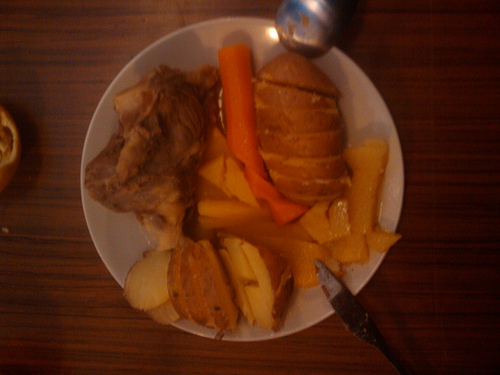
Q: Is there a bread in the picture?
A: Yes, there is a bread.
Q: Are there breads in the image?
A: Yes, there is a bread.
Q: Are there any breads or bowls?
A: Yes, there is a bread.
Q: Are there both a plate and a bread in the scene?
A: Yes, there are both a bread and a plate.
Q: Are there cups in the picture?
A: No, there are no cups.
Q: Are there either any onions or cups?
A: No, there are no cups or onions.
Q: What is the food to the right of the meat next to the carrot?
A: The food is a bread.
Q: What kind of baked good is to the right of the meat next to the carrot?
A: The food is a bread.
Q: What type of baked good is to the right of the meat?
A: The food is a bread.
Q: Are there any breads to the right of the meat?
A: Yes, there is a bread to the right of the meat.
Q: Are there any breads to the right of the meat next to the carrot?
A: Yes, there is a bread to the right of the meat.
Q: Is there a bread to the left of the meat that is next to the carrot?
A: No, the bread is to the right of the meat.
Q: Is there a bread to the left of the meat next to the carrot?
A: No, the bread is to the right of the meat.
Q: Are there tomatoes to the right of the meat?
A: No, there is a bread to the right of the meat.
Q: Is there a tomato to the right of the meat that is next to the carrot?
A: No, there is a bread to the right of the meat.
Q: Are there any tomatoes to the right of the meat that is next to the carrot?
A: No, there is a bread to the right of the meat.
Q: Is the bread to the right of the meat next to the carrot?
A: Yes, the bread is to the right of the meat.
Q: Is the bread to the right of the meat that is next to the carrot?
A: Yes, the bread is to the right of the meat.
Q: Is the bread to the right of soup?
A: No, the bread is to the right of the meat.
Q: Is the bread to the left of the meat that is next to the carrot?
A: No, the bread is to the right of the meat.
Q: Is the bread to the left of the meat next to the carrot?
A: No, the bread is to the right of the meat.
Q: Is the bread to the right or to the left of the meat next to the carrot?
A: The bread is to the right of the meat.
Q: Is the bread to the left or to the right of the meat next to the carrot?
A: The bread is to the right of the meat.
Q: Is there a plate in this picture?
A: Yes, there is a plate.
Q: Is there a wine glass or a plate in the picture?
A: Yes, there is a plate.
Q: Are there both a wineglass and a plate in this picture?
A: No, there is a plate but no wine glasses.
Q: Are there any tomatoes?
A: No, there are no tomatoes.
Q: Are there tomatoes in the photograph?
A: No, there are no tomatoes.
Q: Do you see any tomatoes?
A: No, there are no tomatoes.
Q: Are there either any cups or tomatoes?
A: No, there are no tomatoes or cups.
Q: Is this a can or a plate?
A: This is a plate.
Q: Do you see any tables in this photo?
A: Yes, there is a table.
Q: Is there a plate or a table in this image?
A: Yes, there is a table.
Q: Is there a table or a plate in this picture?
A: Yes, there is a table.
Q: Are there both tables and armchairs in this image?
A: No, there is a table but no armchairs.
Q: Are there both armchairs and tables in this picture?
A: No, there is a table but no armchairs.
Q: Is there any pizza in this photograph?
A: No, there are no pizzas.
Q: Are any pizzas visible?
A: No, there are no pizzas.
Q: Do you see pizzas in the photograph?
A: No, there are no pizzas.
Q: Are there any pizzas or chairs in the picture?
A: No, there are no pizzas or chairs.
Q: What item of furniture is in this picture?
A: The piece of furniture is a table.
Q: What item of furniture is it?
A: The piece of furniture is a table.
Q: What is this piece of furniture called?
A: This is a table.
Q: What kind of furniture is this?
A: This is a table.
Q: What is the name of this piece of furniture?
A: This is a table.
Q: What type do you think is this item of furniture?
A: This is a table.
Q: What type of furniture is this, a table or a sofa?
A: This is a table.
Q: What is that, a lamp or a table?
A: That is a table.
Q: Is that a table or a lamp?
A: That is a table.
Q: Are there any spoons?
A: Yes, there is a spoon.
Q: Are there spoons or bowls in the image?
A: Yes, there is a spoon.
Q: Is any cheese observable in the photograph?
A: No, there is no cheese.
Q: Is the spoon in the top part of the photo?
A: Yes, the spoon is in the top of the image.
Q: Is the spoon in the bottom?
A: No, the spoon is in the top of the image.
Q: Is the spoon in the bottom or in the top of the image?
A: The spoon is in the top of the image.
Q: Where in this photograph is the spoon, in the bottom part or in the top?
A: The spoon is in the top of the image.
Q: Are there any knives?
A: Yes, there is a knife.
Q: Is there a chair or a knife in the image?
A: Yes, there is a knife.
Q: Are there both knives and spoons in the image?
A: Yes, there are both a knife and a spoon.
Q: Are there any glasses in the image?
A: No, there are no glasses.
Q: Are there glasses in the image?
A: No, there are no glasses.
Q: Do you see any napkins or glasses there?
A: No, there are no glasses or napkins.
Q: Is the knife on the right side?
A: Yes, the knife is on the right of the image.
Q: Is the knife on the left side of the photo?
A: No, the knife is on the right of the image.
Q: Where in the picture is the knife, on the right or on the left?
A: The knife is on the right of the image.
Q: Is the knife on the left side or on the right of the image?
A: The knife is on the right of the image.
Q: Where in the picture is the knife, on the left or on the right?
A: The knife is on the right of the image.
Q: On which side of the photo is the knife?
A: The knife is on the right of the image.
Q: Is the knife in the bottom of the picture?
A: Yes, the knife is in the bottom of the image.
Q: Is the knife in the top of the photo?
A: No, the knife is in the bottom of the image.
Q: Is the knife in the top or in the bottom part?
A: The knife is in the bottom of the image.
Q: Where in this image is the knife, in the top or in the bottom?
A: The knife is in the bottom of the image.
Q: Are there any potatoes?
A: Yes, there is a potato.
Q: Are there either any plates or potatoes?
A: Yes, there is a potato.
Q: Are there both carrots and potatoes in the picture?
A: Yes, there are both a potato and carrots.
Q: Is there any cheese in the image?
A: No, there is no cheese.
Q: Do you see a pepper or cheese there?
A: No, there are no cheese or peppers.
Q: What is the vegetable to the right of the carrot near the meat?
A: The vegetable is a potato.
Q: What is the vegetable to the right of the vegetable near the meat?
A: The vegetable is a potato.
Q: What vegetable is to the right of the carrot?
A: The vegetable is a potato.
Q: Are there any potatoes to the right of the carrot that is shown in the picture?
A: Yes, there is a potato to the right of the carrot.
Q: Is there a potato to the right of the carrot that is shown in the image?
A: Yes, there is a potato to the right of the carrot.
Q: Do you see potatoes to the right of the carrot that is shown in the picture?
A: Yes, there is a potato to the right of the carrot.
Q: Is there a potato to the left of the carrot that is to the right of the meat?
A: No, the potato is to the right of the carrot.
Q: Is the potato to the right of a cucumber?
A: No, the potato is to the right of the carrot.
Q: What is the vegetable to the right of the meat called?
A: The vegetable is a potato.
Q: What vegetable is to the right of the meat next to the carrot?
A: The vegetable is a potato.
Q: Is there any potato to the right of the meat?
A: Yes, there is a potato to the right of the meat.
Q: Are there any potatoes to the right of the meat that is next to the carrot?
A: Yes, there is a potato to the right of the meat.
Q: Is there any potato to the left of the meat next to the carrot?
A: No, the potato is to the right of the meat.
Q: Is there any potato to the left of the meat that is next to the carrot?
A: No, the potato is to the right of the meat.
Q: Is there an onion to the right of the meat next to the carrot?
A: No, there is a potato to the right of the meat.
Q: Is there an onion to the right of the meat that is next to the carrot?
A: No, there is a potato to the right of the meat.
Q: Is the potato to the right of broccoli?
A: No, the potato is to the right of the meat.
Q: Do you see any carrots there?
A: Yes, there is a carrot.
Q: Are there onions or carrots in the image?
A: Yes, there is a carrot.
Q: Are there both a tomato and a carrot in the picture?
A: No, there is a carrot but no tomatoes.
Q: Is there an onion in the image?
A: No, there are no onions.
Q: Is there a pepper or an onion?
A: No, there are no onions or peppers.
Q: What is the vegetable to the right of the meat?
A: The vegetable is a carrot.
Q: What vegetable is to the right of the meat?
A: The vegetable is a carrot.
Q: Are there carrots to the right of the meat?
A: Yes, there is a carrot to the right of the meat.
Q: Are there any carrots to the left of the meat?
A: No, the carrot is to the right of the meat.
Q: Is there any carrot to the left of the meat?
A: No, the carrot is to the right of the meat.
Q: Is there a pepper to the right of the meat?
A: No, there is a carrot to the right of the meat.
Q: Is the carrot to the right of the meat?
A: Yes, the carrot is to the right of the meat.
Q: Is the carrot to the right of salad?
A: No, the carrot is to the right of the meat.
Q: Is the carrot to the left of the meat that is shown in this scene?
A: No, the carrot is to the right of the meat.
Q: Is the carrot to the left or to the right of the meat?
A: The carrot is to the right of the meat.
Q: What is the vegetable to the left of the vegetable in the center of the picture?
A: The vegetable is a carrot.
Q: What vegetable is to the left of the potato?
A: The vegetable is a carrot.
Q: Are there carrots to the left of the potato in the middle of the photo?
A: Yes, there is a carrot to the left of the potato.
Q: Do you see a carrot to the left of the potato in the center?
A: Yes, there is a carrot to the left of the potato.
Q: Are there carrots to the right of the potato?
A: No, the carrot is to the left of the potato.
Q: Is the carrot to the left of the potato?
A: Yes, the carrot is to the left of the potato.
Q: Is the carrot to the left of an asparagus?
A: No, the carrot is to the left of the potato.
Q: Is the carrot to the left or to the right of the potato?
A: The carrot is to the left of the potato.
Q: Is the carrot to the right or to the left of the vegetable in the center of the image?
A: The carrot is to the left of the potato.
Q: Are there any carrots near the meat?
A: Yes, there is a carrot near the meat.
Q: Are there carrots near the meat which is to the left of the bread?
A: Yes, there is a carrot near the meat.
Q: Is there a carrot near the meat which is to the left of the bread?
A: Yes, there is a carrot near the meat.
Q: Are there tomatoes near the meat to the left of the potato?
A: No, there is a carrot near the meat.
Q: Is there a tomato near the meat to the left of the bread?
A: No, there is a carrot near the meat.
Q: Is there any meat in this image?
A: Yes, there is meat.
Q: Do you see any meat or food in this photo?
A: Yes, there is meat.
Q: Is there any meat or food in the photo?
A: Yes, there is meat.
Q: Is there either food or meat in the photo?
A: Yes, there is meat.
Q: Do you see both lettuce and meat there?
A: No, there is meat but no lettuce.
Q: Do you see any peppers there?
A: No, there are no peppers.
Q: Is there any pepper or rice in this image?
A: No, there are no peppers or rice.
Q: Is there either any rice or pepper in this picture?
A: No, there are no peppers or rice.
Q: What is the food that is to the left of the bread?
A: The food is meat.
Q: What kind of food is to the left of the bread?
A: The food is meat.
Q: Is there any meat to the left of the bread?
A: Yes, there is meat to the left of the bread.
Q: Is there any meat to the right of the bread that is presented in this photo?
A: No, the meat is to the left of the bread.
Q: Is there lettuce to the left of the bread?
A: No, there is meat to the left of the bread.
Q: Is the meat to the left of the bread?
A: Yes, the meat is to the left of the bread.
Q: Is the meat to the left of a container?
A: No, the meat is to the left of the bread.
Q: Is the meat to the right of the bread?
A: No, the meat is to the left of the bread.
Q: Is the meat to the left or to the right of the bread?
A: The meat is to the left of the bread.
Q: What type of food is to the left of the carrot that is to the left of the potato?
A: The food is meat.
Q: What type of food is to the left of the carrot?
A: The food is meat.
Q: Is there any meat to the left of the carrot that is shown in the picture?
A: Yes, there is meat to the left of the carrot.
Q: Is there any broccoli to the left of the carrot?
A: No, there is meat to the left of the carrot.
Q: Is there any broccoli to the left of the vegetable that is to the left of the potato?
A: No, there is meat to the left of the carrot.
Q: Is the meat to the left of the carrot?
A: Yes, the meat is to the left of the carrot.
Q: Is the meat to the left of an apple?
A: No, the meat is to the left of the carrot.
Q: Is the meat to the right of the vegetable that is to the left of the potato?
A: No, the meat is to the left of the carrot.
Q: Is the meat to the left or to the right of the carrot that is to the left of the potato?
A: The meat is to the left of the carrot.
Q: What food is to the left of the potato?
A: The food is meat.